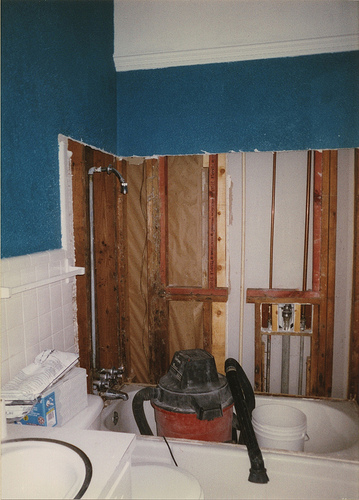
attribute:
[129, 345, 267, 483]
vacuum — one, large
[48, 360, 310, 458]
bathtub — in tub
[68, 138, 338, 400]
wall — gutted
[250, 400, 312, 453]
bucket — one, plastic, white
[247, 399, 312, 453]
industrial bucket — white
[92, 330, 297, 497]
vacuum cleaner — in tub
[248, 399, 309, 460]
bucket — white, handled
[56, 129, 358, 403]
shower wall — in tub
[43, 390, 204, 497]
toilet — white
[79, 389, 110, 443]
tank — white, toliet's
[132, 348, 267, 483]
vacuum cleaner — in tub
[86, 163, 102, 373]
pipe — in tub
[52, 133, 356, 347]
wall — gutted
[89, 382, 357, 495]
tub — in tub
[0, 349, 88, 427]
package — assorted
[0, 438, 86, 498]
sink — white, one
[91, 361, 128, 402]
fixtures — metal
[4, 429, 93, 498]
trim — black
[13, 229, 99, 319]
towel bar — white, ceramic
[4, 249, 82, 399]
square tiles — white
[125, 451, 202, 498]
toilet — white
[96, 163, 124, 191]
shower head — silver